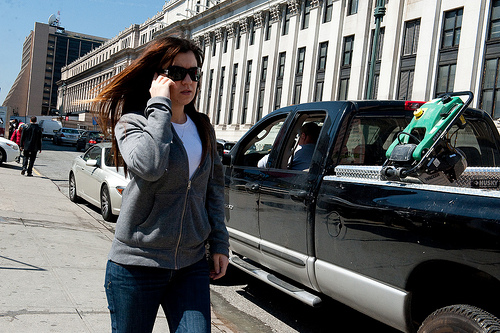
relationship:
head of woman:
[148, 36, 204, 112] [104, 35, 230, 333]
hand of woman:
[207, 251, 229, 282] [104, 35, 230, 333]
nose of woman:
[180, 73, 194, 87] [104, 35, 230, 333]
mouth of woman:
[178, 87, 194, 97] [104, 35, 230, 333]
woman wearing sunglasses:
[104, 35, 230, 333] [158, 63, 203, 83]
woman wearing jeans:
[104, 35, 230, 333] [104, 258, 210, 332]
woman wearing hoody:
[104, 35, 230, 333] [107, 96, 230, 268]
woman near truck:
[104, 35, 230, 333] [222, 99, 499, 331]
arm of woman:
[114, 97, 171, 182] [104, 35, 230, 333]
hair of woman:
[92, 36, 215, 176] [104, 35, 230, 333]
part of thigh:
[110, 292, 138, 307] [104, 281, 161, 333]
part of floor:
[1, 220, 33, 270] [0, 160, 228, 332]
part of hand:
[161, 90, 169, 96] [147, 73, 175, 99]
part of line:
[19, 222, 39, 239] [1, 184, 98, 333]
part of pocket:
[161, 228, 175, 244] [135, 192, 212, 249]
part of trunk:
[67, 134, 74, 139] [62, 132, 81, 141]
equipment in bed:
[382, 91, 471, 185] [321, 166, 499, 199]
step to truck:
[230, 252, 323, 308] [222, 99, 499, 331]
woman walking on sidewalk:
[104, 35, 230, 333] [0, 160, 228, 332]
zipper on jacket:
[172, 176, 195, 271] [107, 96, 230, 268]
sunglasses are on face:
[158, 63, 203, 83] [169, 51, 202, 103]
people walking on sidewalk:
[8, 115, 43, 177] [0, 160, 228, 332]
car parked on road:
[67, 141, 135, 220] [15, 139, 399, 332]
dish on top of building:
[46, 10, 63, 28] [0, 21, 112, 115]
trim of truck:
[225, 225, 407, 333] [222, 99, 499, 331]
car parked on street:
[67, 141, 135, 220] [15, 139, 399, 332]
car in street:
[51, 126, 84, 146] [15, 139, 399, 332]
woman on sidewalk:
[104, 35, 230, 333] [0, 160, 228, 332]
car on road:
[67, 141, 135, 220] [15, 139, 399, 332]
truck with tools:
[222, 99, 499, 331] [333, 166, 499, 195]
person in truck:
[255, 122, 319, 170] [222, 99, 499, 331]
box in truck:
[333, 166, 499, 195] [222, 99, 499, 331]